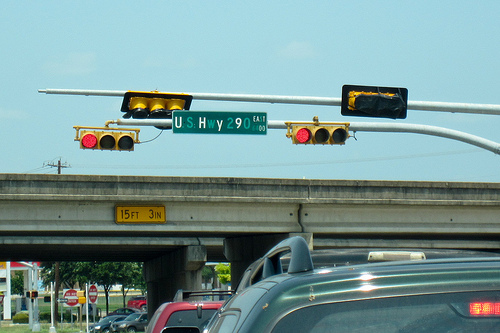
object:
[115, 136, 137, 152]
traffic light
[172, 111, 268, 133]
street sign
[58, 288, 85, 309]
sign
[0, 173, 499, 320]
bridge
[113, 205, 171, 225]
sign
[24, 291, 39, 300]
pedestrian sign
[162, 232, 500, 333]
minivan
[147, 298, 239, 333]
van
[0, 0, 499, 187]
sky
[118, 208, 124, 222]
black writing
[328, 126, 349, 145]
traffic light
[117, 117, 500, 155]
pole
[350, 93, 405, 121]
black cover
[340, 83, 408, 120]
traffic light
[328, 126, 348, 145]
lights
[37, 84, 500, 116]
pole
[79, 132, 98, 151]
light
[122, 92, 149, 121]
street light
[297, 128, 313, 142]
light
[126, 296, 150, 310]
car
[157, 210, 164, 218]
letters on sign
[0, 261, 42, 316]
building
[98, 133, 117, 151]
traffic signal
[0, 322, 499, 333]
road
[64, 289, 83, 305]
do not enter sign